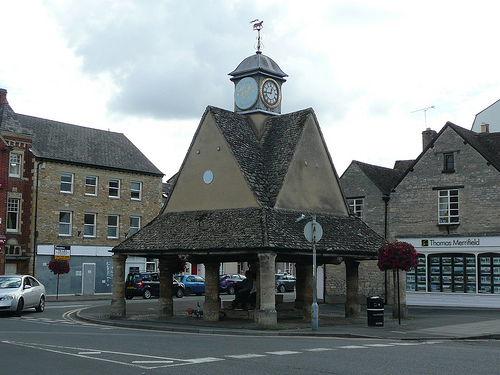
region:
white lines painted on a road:
[170, 338, 421, 374]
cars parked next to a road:
[121, 266, 300, 302]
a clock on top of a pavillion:
[232, 27, 292, 127]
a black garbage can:
[361, 289, 389, 339]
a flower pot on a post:
[46, 242, 70, 299]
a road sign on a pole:
[301, 209, 329, 326]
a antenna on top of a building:
[410, 92, 443, 144]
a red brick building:
[0, 119, 35, 259]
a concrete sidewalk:
[381, 315, 497, 351]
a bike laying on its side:
[178, 293, 220, 326]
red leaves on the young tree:
[379, 240, 423, 267]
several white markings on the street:
[215, 339, 426, 359]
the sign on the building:
[420, 237, 496, 251]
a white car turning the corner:
[2, 275, 44, 310]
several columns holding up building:
[116, 253, 275, 325]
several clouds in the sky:
[13, 18, 111, 92]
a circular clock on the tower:
[262, 78, 284, 112]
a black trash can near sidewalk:
[367, 299, 384, 324]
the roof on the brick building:
[35, 116, 129, 161]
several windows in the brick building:
[62, 173, 145, 200]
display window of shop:
[441, 255, 489, 325]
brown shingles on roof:
[263, 153, 288, 182]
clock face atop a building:
[265, 88, 302, 108]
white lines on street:
[211, 335, 242, 365]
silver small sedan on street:
[16, 274, 33, 316]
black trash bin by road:
[364, 296, 384, 343]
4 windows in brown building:
[58, 171, 146, 198]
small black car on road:
[131, 275, 184, 292]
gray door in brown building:
[83, 260, 96, 302]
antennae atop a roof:
[407, 99, 459, 147]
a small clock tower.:
[224, 9, 299, 123]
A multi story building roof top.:
[12, 102, 169, 179]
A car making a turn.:
[0, 261, 52, 330]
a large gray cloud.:
[39, 1, 399, 128]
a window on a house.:
[423, 178, 465, 236]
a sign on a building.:
[38, 227, 75, 285]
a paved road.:
[0, 309, 497, 373]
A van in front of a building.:
[124, 270, 211, 305]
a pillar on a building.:
[249, 232, 288, 329]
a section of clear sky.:
[318, 15, 383, 42]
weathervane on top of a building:
[242, 12, 274, 52]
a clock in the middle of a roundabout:
[224, 45, 296, 120]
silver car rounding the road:
[2, 259, 56, 322]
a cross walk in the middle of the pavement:
[134, 336, 494, 371]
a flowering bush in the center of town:
[373, 236, 423, 278]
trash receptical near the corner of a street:
[364, 293, 389, 327]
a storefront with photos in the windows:
[400, 233, 496, 296]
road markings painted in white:
[5, 332, 430, 369]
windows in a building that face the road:
[53, 170, 145, 242]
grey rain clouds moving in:
[75, 3, 207, 108]